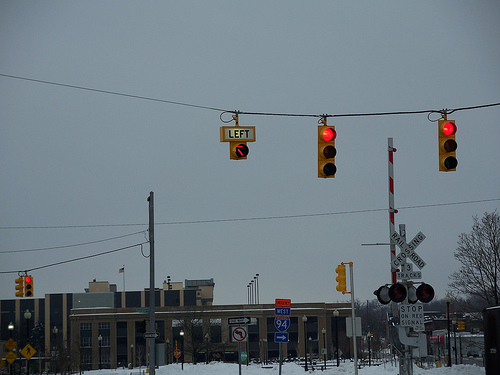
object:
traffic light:
[436, 119, 459, 174]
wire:
[1, 72, 500, 117]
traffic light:
[317, 124, 337, 178]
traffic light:
[216, 113, 256, 163]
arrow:
[235, 146, 246, 157]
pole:
[385, 136, 396, 283]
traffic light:
[335, 263, 345, 293]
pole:
[347, 262, 361, 375]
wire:
[0, 239, 154, 276]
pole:
[148, 191, 157, 374]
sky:
[0, 0, 496, 303]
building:
[1, 278, 360, 374]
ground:
[37, 348, 500, 375]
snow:
[83, 357, 486, 375]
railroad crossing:
[375, 224, 435, 375]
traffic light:
[14, 274, 24, 299]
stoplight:
[24, 275, 32, 282]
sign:
[274, 309, 290, 345]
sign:
[19, 345, 39, 360]